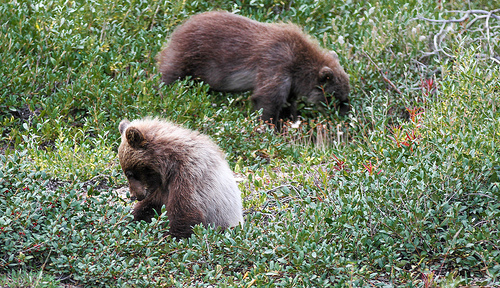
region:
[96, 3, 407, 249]
Two Baby Bears laying in grass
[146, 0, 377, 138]
Baby bear is on all four legs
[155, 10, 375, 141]
Bears face is in the plants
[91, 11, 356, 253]
Bears fur is brown in color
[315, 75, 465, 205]
Plants on the right have a red tip on end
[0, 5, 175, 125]
Plants in background is a bright green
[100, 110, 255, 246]
Baby Bear is lean over in the plants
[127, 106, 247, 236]
Baby bears fur is lighter due to sunlight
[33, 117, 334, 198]
Plants have a yellowish colored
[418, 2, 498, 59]
This plant is bare in background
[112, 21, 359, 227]
Two bears are seen.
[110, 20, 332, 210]
bears are brown in color.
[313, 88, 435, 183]
red color flowers are seen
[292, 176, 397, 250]
plants are green in color.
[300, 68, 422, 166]
bear is eating.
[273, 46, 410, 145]
bear is eating.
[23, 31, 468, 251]
day time picture.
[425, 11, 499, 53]
twig is brown in color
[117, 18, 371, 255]
two bears are facing opposite side.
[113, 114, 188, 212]
bear is looking down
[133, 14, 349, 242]
two bears in the grass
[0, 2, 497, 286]
the plants are green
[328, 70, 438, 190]
red flowers grow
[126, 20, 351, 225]
the bears are brown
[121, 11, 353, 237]
the bears are babies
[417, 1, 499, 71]
brown twigs in the grass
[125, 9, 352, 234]
the bears are looking down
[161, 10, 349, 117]
the bear is dark brown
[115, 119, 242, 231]
the bear is light brown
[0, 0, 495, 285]
the scene takes place outside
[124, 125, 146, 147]
brown ear on bear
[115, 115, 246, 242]
bear is bent over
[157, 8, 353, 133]
bear has nose buried in ground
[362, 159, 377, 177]
red flower on floor covering plant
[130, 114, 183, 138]
neck has tufts of fur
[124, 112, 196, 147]
sun shining on bears neck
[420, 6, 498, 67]
twigs laying on ground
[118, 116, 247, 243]
bear is looking at the ground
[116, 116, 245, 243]
bear is sitting up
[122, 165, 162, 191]
dark fur around bears nose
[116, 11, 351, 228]
Two young baby brown bears.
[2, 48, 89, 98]
A patch of green grass.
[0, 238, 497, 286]
A patch of grass with different colored plant life.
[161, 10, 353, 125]
a brown bear with face in the grass.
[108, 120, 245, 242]
A brown bear sitting on the grass.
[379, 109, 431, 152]
Orange colored wild plant life.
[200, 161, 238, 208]
Light fur on the brown bears back.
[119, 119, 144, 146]
The brown bears ears.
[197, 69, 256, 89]
The brown bears tummy with light colored fur.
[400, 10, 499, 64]
White branches on the ground.